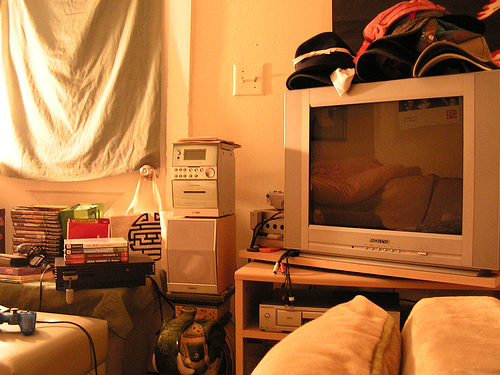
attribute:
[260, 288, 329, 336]
dvd player — silver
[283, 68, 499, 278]
tv — off, silver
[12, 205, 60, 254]
video games — stacked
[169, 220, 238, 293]
speaker — silver, large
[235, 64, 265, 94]
light switch — paired, white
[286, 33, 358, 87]
hat — piled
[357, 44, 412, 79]
hat — stacked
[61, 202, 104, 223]
bag — green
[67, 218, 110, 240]
bag — red